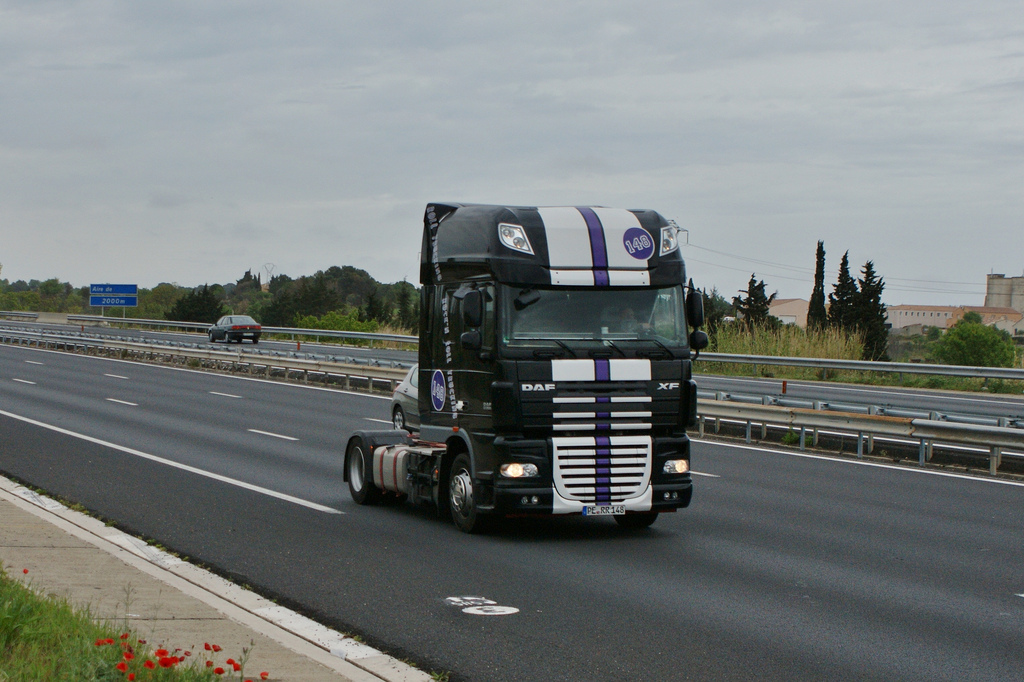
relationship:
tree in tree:
[236, 239, 431, 326] [276, 265, 423, 336]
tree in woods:
[807, 240, 827, 342] [823, 256, 970, 416]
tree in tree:
[733, 256, 820, 350] [731, 272, 783, 331]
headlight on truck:
[663, 460, 688, 474] [340, 172, 691, 540]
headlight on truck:
[499, 463, 538, 477] [358, 187, 704, 518]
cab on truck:
[493, 285, 690, 359] [378, 170, 705, 538]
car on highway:
[192, 315, 266, 341] [23, 317, 248, 510]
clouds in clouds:
[192, 56, 264, 121] [0, 0, 1024, 307]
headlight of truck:
[485, 455, 540, 499] [378, 170, 705, 538]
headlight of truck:
[645, 459, 704, 477] [343, 170, 707, 520]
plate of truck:
[580, 492, 630, 525] [356, 159, 717, 535]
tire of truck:
[324, 419, 383, 506] [358, 187, 704, 518]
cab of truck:
[493, 285, 690, 359] [392, 179, 715, 532]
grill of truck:
[542, 358, 646, 484] [423, 192, 698, 543]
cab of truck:
[466, 215, 676, 304] [408, 209, 705, 527]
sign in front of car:
[81, 278, 151, 309] [200, 302, 265, 354]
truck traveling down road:
[393, 198, 705, 507] [53, 334, 231, 484]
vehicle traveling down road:
[378, 351, 418, 421] [708, 505, 948, 665]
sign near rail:
[88, 283, 138, 308] [64, 317, 151, 365]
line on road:
[69, 425, 214, 493] [97, 364, 257, 501]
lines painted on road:
[103, 384, 296, 434] [94, 390, 304, 525]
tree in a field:
[803, 220, 847, 342] [727, 272, 916, 366]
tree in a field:
[731, 272, 783, 331] [719, 282, 888, 367]